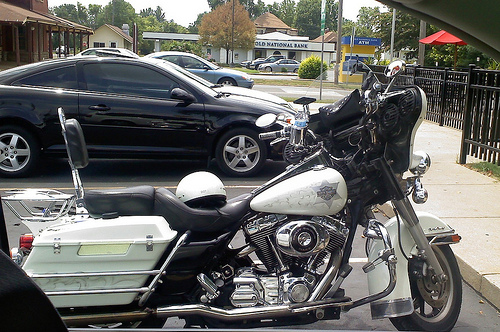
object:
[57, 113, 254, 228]
seat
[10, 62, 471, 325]
motorcycle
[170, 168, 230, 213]
helmet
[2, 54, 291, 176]
car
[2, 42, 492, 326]
lot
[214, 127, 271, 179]
wheel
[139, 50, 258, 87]
car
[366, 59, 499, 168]
fence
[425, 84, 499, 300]
sidewalk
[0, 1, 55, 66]
building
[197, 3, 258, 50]
leaves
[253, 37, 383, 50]
writing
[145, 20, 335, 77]
building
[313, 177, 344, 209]
star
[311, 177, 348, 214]
points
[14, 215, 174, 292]
case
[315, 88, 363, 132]
case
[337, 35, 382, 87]
atm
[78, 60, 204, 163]
door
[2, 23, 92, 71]
porch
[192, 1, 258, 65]
tree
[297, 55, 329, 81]
bush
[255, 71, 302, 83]
sidewalk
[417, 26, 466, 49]
umbrella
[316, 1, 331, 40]
sign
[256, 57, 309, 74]
cars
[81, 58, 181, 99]
window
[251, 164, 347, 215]
tank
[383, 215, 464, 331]
wheel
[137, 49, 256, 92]
cars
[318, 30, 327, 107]
pole